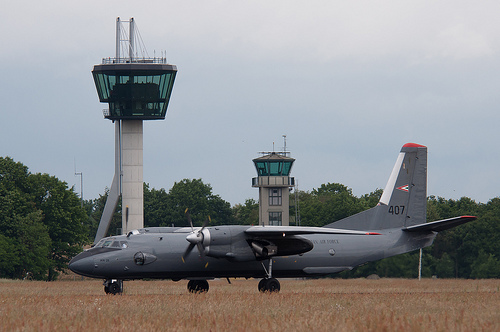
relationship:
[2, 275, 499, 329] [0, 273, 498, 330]
brown grass in field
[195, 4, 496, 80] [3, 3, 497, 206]
clouds in sky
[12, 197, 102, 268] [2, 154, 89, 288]
leaves on tree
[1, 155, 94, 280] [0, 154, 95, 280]
leaves on tree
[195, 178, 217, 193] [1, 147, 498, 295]
tree on leaves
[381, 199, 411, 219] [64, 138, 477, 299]
numbers on plane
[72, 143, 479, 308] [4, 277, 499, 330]
grey airplane sitting on runway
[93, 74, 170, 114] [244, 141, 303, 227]
windows on tower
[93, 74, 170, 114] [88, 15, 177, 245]
windows on tower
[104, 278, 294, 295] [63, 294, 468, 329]
wheels touching ground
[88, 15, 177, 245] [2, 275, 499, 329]
tower in brown grass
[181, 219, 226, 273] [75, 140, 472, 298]
propeller on airplane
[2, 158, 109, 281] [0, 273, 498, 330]
trees alongside field